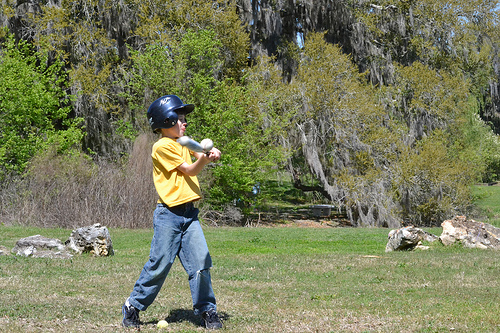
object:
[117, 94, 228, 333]
boy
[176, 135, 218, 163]
bat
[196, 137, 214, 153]
ball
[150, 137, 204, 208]
shirt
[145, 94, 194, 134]
helmet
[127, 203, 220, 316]
jeans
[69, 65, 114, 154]
tree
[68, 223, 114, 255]
rock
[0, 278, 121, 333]
grass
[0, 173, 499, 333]
ground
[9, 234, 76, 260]
rock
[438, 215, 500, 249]
rock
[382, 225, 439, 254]
rock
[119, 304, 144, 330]
shoe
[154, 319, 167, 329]
ball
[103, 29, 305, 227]
tree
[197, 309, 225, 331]
shoe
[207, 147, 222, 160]
hands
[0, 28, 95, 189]
tree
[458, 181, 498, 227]
grass